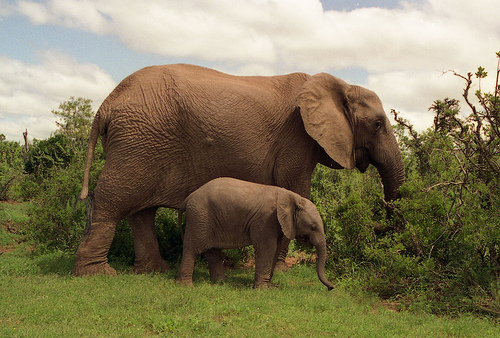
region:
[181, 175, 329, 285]
Baby elephant beside it's mother.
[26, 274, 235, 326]
The grass is green.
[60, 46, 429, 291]
Two elephants in the shot.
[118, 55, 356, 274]
The elephants are brown.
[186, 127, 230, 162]
Bump on the large elephant.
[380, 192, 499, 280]
The leaves are green.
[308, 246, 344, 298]
The trunk is small.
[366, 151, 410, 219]
The trunk is large.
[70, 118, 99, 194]
The tail is thin.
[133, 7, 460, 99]
Clouds in the sky.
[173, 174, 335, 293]
a baby elephant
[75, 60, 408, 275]
a mother elephant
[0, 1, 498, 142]
a cloudy blue sky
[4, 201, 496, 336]
a green grassy area around two elephants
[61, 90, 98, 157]
a tree behind two elephants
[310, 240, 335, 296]
the trunk of a baby elephant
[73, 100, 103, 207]
the tail of an adult elephant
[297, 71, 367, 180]
the ear of an elephant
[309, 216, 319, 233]
the eye of a baby elephant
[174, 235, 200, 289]
the hind leg of a baby elephant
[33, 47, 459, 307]
Two elephants are together.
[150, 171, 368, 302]
The smaller elephant is a baby.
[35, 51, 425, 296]
The larger elephant is the mother.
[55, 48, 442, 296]
The elephants are facing right.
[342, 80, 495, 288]
The elephant's trunk is in the bushes.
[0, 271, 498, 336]
The elephants stand on grass.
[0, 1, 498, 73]
The sky is partly cloudy.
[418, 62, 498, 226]
The tree has bare branches.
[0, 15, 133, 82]
The sky is blue.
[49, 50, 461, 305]
The elephants are brown.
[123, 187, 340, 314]
baby elephant with mom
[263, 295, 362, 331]
grass under the elephant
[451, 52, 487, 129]
tree branch in the air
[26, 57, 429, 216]
mother elephant wit baby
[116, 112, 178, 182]
wrinkles in the skin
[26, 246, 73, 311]
shadow of the elephant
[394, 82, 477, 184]
trees next to elephant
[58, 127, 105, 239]
tail of the elephant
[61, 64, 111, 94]
clouds in the sky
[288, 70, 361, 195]
ear of the elephant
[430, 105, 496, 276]
the plants are visible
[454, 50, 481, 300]
the plants are visible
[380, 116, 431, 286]
the plants are visible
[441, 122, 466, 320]
the plants are visible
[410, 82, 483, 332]
the plants are visible